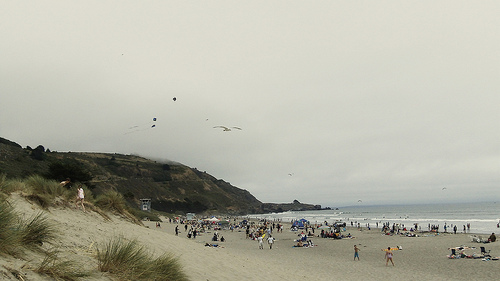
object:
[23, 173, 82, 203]
grass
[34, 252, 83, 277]
grass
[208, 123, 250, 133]
bird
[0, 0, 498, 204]
clouds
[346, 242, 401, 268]
two little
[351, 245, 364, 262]
person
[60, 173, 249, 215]
hillside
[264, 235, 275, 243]
shirt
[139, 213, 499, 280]
beach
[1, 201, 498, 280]
sand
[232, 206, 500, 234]
ocean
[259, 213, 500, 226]
wave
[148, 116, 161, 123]
back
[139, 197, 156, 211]
tower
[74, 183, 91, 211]
people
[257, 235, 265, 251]
people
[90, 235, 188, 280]
grass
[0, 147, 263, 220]
hill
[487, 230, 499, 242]
people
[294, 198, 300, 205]
rock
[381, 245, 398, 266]
person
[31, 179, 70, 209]
patch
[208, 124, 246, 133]
flight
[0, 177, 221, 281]
dune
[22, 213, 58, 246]
grass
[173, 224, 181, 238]
people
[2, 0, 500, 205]
sky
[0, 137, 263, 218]
greenery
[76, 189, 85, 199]
shirt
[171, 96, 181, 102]
kite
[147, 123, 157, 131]
kite